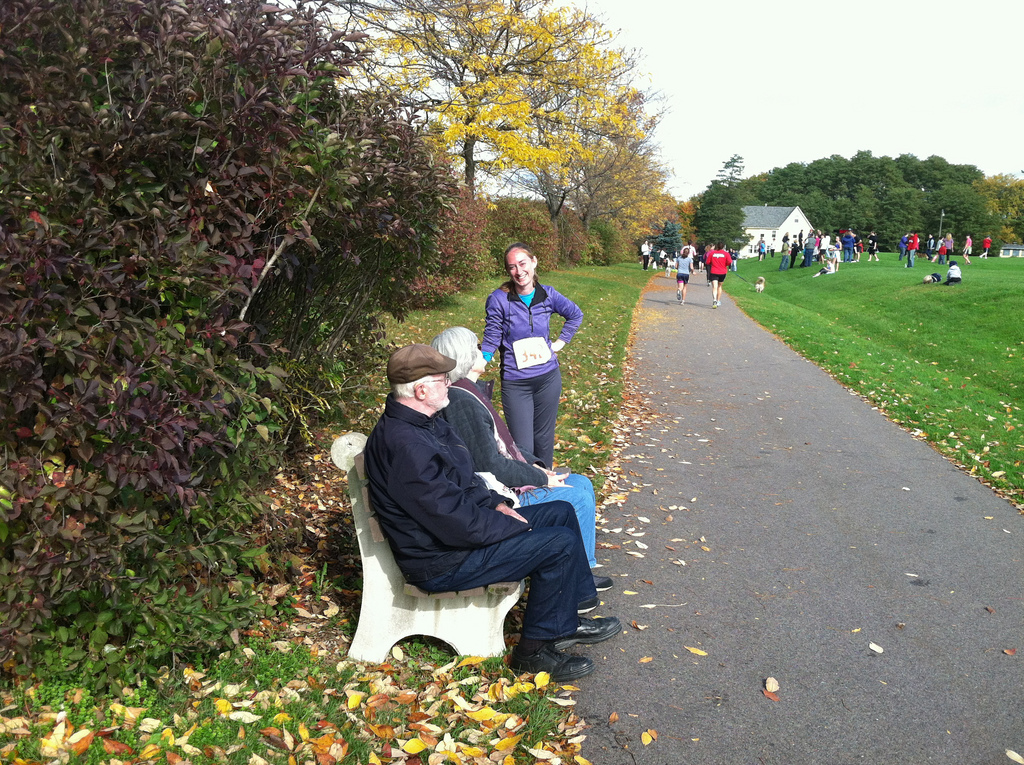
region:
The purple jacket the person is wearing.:
[463, 283, 578, 372]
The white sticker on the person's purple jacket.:
[512, 338, 552, 367]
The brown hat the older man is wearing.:
[383, 338, 459, 376]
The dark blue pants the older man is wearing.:
[459, 502, 599, 657]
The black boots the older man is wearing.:
[512, 601, 620, 685]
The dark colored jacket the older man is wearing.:
[365, 399, 511, 559]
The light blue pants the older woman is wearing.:
[512, 467, 590, 572]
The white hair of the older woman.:
[438, 329, 473, 367]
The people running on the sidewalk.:
[626, 212, 737, 314]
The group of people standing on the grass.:
[751, 221, 1011, 297]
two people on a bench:
[326, 328, 618, 692]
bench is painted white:
[329, 427, 526, 663]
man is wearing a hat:
[357, 341, 623, 681]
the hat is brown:
[382, 339, 456, 390]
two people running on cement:
[661, 239, 739, 312]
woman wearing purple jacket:
[479, 243, 585, 468]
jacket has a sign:
[482, 285, 584, 385]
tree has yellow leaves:
[299, 4, 661, 280]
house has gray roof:
[730, 198, 820, 265]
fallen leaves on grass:
[0, 258, 640, 762]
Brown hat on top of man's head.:
[403, 341, 445, 374]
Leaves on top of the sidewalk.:
[752, 659, 782, 689]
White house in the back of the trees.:
[733, 192, 822, 256]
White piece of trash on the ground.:
[300, 415, 367, 476]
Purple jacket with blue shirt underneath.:
[463, 283, 588, 394]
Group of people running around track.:
[673, 235, 734, 300]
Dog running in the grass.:
[748, 265, 778, 300]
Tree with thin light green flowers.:
[397, 11, 614, 183]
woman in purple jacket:
[482, 244, 584, 469]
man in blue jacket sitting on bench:
[361, 347, 593, 677]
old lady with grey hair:
[430, 322, 607, 572]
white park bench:
[333, 432, 527, 663]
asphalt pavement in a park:
[555, 260, 1021, 754]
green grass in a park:
[699, 262, 1022, 518]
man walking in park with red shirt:
[708, 244, 731, 308]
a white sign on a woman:
[513, 335, 552, 371]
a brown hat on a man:
[381, 341, 454, 383]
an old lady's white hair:
[434, 328, 479, 379]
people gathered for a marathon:
[634, 222, 998, 309]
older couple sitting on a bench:
[329, 320, 624, 678]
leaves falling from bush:
[2, 655, 562, 761]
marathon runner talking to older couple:
[362, 237, 616, 686]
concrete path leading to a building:
[561, 268, 1023, 762]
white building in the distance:
[738, 200, 818, 258]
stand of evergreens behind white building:
[689, 148, 999, 251]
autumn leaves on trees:
[384, 3, 699, 298]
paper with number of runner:
[509, 333, 555, 368]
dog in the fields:
[752, 272, 768, 293]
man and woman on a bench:
[348, 337, 606, 666]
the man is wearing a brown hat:
[386, 348, 456, 412]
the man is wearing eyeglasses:
[384, 353, 455, 411]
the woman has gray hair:
[431, 328, 489, 379]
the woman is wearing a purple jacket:
[472, 247, 589, 375]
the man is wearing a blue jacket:
[368, 348, 517, 545]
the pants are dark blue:
[457, 502, 600, 636]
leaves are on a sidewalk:
[620, 356, 694, 527]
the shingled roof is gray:
[741, 200, 792, 232]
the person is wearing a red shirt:
[712, 252, 735, 275]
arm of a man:
[386, 439, 523, 542]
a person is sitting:
[371, 353, 603, 687]